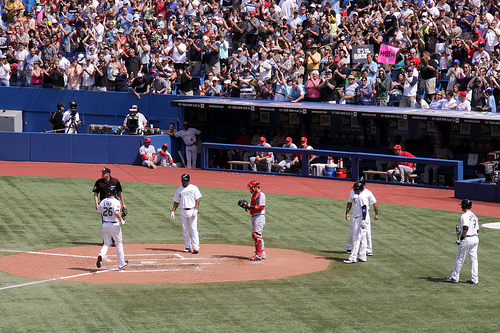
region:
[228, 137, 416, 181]
Four baseball players sitting on benches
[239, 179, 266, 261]
Baseball player in red padding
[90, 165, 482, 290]
Seven people on a baseball field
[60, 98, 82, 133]
Man taking pictures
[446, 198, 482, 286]
Baseball player in a white uniform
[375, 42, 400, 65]
Homemade pink sign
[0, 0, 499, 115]
People in the bleachers watching a baseball game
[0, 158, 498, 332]
Green turf baseball field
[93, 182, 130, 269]
Baseball player running to a base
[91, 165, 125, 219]
Man in a black hat and shirt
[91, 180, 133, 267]
baseball player in uniform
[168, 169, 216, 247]
baseball player in uniform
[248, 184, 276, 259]
baseball player in uniform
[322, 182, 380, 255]
baseball player in uniform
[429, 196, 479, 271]
baseball player in uniform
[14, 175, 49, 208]
short green and brown grass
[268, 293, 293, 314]
short green and brown grass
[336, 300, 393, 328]
short green and brown grass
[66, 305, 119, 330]
short green and brown grass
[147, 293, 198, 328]
short green and brown grass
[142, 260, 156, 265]
Home plate in a baseball diamond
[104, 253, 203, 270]
Batter's box in a baseball diamond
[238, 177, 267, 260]
Catcher in a baseball game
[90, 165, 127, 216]
Umpire in a baseball game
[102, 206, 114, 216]
Number on a baseball players jersey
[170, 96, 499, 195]
Dugout for the baseball team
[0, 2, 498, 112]
Spectators at a baseball game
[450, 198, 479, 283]
Baseball player carrying a bat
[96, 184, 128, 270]
Baserunner heading for home plate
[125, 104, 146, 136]
Camera and cameraman at a baseball game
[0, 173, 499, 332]
grassy surface on a baseball field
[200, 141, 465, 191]
blue fence in front of a dugout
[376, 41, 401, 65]
pink sign in the cheering crowd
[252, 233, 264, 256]
red leg pad on the catcher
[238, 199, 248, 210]
mitt on catcher's bent arm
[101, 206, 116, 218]
number 26 on the back of a player's uniform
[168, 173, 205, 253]
player standing directly in front of the catcher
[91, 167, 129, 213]
man on the field in a black cap and black shirt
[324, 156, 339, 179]
blue water cooler in the dugout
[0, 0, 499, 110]
fans watching the game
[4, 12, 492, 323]
picture taken at a baseball field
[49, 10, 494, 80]
spectators in the stands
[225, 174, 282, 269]
catcher wearing red protective equipment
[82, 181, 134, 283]
baseball player running to home plate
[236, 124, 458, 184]
baseball players in teh bullpen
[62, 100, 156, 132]
two people videotaping the baseball game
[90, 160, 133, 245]
baseball umpire wearing a black shirt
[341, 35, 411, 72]
baseball fans holding up signs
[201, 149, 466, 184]
blue fence in front of the bullpen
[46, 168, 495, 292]
7 people standing on the baseball field